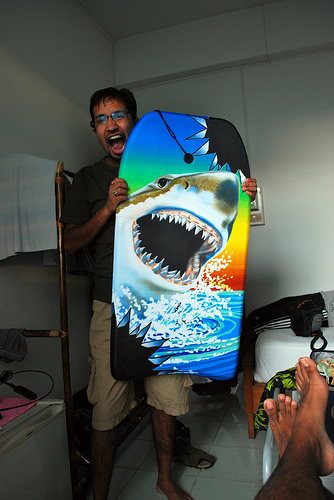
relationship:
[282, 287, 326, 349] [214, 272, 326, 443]
camera on bed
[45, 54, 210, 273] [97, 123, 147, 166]
man with mouth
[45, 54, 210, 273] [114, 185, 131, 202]
man with ring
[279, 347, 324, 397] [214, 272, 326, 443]
pillow and bed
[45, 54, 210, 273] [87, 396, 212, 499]
man has leg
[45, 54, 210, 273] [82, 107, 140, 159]
man has face